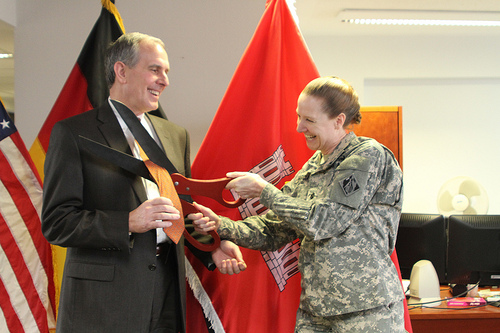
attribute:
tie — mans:
[128, 118, 197, 276]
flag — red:
[179, 4, 339, 331]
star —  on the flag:
[1, 113, 11, 133]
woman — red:
[181, 70, 408, 330]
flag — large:
[174, 0, 413, 329]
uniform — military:
[240, 148, 457, 330]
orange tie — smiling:
[107, 110, 187, 250]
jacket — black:
[33, 109, 183, 291]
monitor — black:
[441, 216, 498, 280]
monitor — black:
[382, 208, 447, 276]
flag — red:
[180, 0, 362, 276]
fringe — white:
[169, 262, 241, 329]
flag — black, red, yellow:
[23, 6, 147, 191]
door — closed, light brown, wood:
[339, 107, 403, 207]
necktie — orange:
[131, 155, 188, 236]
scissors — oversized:
[86, 96, 254, 247]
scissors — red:
[85, 98, 251, 231]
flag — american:
[0, 95, 60, 329]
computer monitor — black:
[381, 212, 446, 282]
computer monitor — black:
[441, 208, 498, 273]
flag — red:
[168, 5, 319, 327]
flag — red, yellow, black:
[26, 0, 164, 171]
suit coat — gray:
[41, 106, 220, 329]